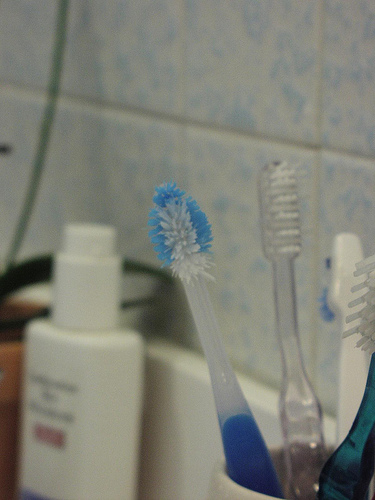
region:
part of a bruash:
[234, 445, 261, 465]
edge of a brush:
[209, 414, 229, 456]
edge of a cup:
[224, 475, 247, 496]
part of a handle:
[102, 425, 132, 459]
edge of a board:
[130, 412, 148, 446]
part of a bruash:
[222, 420, 251, 470]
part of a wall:
[158, 429, 184, 470]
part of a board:
[78, 399, 121, 444]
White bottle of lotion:
[18, 220, 159, 490]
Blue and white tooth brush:
[144, 217, 283, 487]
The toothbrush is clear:
[252, 217, 329, 477]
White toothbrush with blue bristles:
[313, 228, 370, 445]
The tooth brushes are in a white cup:
[143, 216, 370, 491]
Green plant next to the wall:
[15, 41, 176, 332]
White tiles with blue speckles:
[93, 30, 360, 233]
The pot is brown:
[4, 281, 61, 479]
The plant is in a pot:
[6, 56, 81, 389]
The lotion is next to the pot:
[14, 208, 167, 491]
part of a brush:
[230, 420, 256, 453]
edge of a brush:
[212, 432, 233, 464]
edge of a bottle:
[112, 410, 158, 465]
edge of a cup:
[218, 476, 235, 486]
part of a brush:
[278, 413, 303, 447]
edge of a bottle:
[119, 410, 139, 457]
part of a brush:
[206, 334, 239, 372]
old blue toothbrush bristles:
[152, 185, 266, 310]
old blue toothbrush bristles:
[112, 162, 215, 273]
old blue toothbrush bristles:
[151, 201, 222, 291]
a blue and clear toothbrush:
[149, 182, 272, 480]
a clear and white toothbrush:
[253, 155, 323, 490]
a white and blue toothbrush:
[310, 236, 371, 443]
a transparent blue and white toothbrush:
[315, 247, 373, 491]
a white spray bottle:
[12, 212, 139, 499]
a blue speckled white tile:
[168, 125, 312, 377]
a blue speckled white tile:
[90, 103, 184, 334]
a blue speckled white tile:
[184, 0, 324, 153]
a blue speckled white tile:
[75, 2, 182, 120]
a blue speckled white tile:
[316, 144, 373, 407]